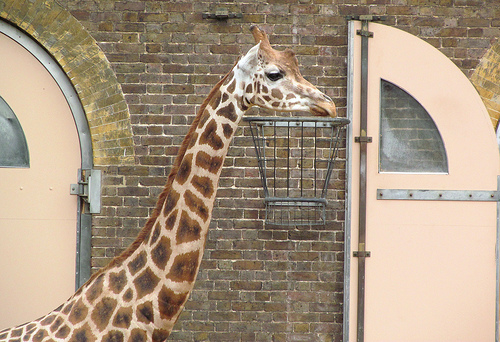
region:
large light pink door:
[341, 14, 497, 334]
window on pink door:
[362, 58, 453, 186]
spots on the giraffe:
[101, 249, 171, 334]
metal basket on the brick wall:
[249, 112, 345, 242]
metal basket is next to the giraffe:
[244, 101, 346, 234]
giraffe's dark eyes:
[264, 54, 291, 85]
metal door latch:
[69, 161, 126, 222]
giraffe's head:
[211, 23, 368, 120]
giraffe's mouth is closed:
[301, 90, 350, 132]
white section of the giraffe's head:
[226, 50, 263, 80]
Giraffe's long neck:
[99, 103, 251, 275]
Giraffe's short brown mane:
[105, 55, 240, 269]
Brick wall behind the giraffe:
[0, 0, 499, 341]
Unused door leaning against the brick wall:
[345, 21, 499, 341]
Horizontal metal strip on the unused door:
[373, 186, 498, 202]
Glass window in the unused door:
[376, 78, 447, 175]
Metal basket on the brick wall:
[242, 115, 350, 227]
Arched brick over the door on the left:
[0, 1, 136, 166]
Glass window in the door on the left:
[1, 98, 31, 169]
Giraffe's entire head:
[237, 22, 336, 117]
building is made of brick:
[120, 7, 350, 332]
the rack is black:
[255, 117, 340, 249]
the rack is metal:
[250, 113, 332, 212]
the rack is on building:
[245, 105, 352, 228]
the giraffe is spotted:
[130, 80, 285, 337]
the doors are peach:
[355, 81, 498, 337]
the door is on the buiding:
[343, 76, 488, 333]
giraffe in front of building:
[147, 80, 194, 340]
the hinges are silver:
[76, 161, 107, 217]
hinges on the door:
[74, 167, 104, 227]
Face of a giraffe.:
[177, 16, 348, 128]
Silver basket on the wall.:
[242, 114, 357, 240]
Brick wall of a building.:
[87, 8, 191, 163]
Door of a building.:
[343, 15, 483, 340]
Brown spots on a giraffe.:
[148, 221, 198, 291]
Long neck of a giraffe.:
[121, 87, 240, 324]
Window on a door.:
[378, 76, 453, 186]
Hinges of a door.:
[64, 166, 116, 222]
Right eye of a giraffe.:
[257, 65, 292, 86]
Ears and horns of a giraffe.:
[242, 24, 299, 69]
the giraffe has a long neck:
[156, 110, 196, 277]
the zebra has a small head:
[245, 19, 346, 114]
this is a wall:
[138, 24, 180, 109]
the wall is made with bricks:
[231, 239, 299, 312]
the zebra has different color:
[91, 275, 165, 333]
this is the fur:
[163, 180, 168, 191]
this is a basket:
[242, 113, 350, 228]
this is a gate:
[348, 21, 490, 340]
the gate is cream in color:
[390, 228, 446, 319]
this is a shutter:
[82, 169, 102, 211]